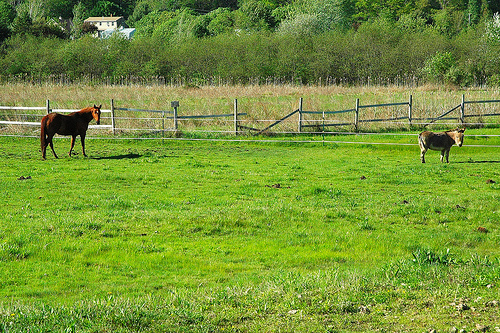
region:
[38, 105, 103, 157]
brown horse in grass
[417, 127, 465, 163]
grey and brown donkey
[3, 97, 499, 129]
grey wooden fence by field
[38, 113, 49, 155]
brown tail of horse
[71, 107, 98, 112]
brown mane of horse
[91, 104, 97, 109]
brown ear on horse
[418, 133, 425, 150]
grey tail on donkey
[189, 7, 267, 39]
tree with green leaves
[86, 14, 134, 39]
white and tan house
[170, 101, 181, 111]
sign on fence post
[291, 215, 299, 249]
part of a grass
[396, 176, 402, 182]
part of a horse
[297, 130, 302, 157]
part of a fence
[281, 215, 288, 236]
edge of a lawn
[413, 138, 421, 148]
part of a tail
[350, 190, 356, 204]
part of a grass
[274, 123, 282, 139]
part of a fence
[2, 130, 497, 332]
grass pasture in the foreground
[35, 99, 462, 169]
two equines in a grass pasture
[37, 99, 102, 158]
brown horse in the grass pasture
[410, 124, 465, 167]
brown donkey in the grass pasture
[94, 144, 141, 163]
shadow of the horse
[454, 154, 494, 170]
shadow of the donkey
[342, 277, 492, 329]
rocks in the grass pasture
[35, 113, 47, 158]
brown hair of horse's tail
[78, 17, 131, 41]
white house in the distance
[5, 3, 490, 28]
trees around the house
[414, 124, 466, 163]
a small horse in a field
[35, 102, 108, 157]
a large brown horse in a field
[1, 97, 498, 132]
wooden fence around the field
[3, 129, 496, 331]
green pasture with grass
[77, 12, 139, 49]
a house between the bushes outside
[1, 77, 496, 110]
a field of weeds behind the fence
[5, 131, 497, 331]
green grass on the ground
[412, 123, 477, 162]
small horse grazing in a field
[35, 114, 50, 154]
long brown horse tail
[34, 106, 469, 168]
two horses in a field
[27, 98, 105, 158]
brown horse with brown mane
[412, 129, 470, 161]
brown donkey in the pasture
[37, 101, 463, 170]
two animals in the pasture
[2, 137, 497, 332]
grass pasture animals are in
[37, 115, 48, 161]
brown tail of the horse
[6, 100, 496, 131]
fence along the grass pasture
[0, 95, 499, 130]
wood posts of the fence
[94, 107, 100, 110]
white spot on horse's face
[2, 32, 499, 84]
line of bushes